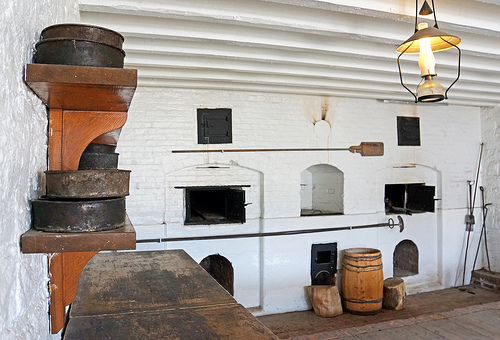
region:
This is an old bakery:
[16, 15, 485, 323]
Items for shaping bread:
[25, 17, 163, 263]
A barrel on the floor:
[283, 228, 416, 333]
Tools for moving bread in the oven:
[450, 138, 499, 250]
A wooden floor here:
[250, 308, 499, 338]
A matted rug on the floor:
[283, 320, 495, 339]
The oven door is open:
[158, 156, 264, 240]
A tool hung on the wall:
[161, 136, 422, 165]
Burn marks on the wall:
[286, 94, 361, 152]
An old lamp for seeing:
[368, 13, 473, 109]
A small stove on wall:
[170, 166, 278, 316]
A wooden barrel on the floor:
[340, 247, 387, 322]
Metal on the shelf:
[12, 160, 180, 290]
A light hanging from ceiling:
[375, 14, 479, 161]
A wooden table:
[102, 258, 187, 336]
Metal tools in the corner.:
[460, 130, 499, 315]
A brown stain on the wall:
[299, 87, 347, 149]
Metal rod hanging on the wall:
[142, 221, 418, 243]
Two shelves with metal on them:
[36, 5, 166, 262]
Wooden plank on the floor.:
[367, 313, 498, 335]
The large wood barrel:
[340, 246, 385, 314]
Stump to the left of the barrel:
[303, 278, 344, 323]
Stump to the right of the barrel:
[380, 274, 409, 309]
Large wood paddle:
[169, 138, 386, 163]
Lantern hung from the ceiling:
[390, 0, 469, 105]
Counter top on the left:
[60, 248, 286, 339]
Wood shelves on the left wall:
[17, 60, 142, 326]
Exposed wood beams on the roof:
[77, 0, 499, 112]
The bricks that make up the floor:
[275, 298, 497, 339]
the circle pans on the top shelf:
[28, 19, 130, 69]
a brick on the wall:
[121, 150, 130, 155]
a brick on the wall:
[136, 157, 149, 170]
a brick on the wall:
[143, 178, 159, 188]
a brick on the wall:
[137, 88, 147, 96]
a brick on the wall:
[160, 105, 175, 117]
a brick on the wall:
[137, 125, 162, 135]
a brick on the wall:
[136, 118, 146, 123]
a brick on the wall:
[172, 116, 187, 126]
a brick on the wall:
[186, 155, 196, 163]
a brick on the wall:
[280, 187, 290, 197]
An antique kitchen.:
[37, 25, 489, 331]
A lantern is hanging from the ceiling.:
[385, 0, 461, 110]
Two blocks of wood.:
[300, 275, 406, 320]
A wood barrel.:
[340, 240, 386, 320]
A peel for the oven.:
[162, 130, 388, 166]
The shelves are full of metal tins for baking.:
[15, 15, 151, 332]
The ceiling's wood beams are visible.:
[141, 0, 492, 102]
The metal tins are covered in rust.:
[25, 150, 131, 245]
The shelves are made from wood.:
[16, 35, 151, 325]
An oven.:
[161, 165, 266, 251]